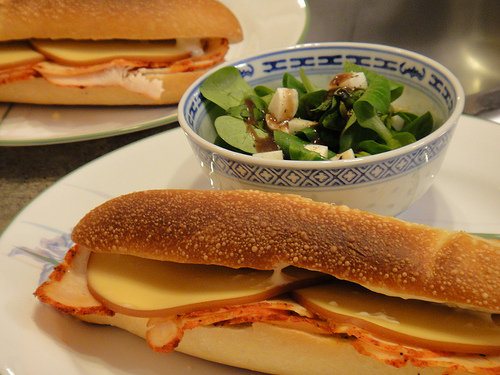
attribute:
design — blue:
[383, 144, 415, 180]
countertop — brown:
[13, 177, 25, 186]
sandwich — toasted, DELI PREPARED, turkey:
[38, 191, 499, 372]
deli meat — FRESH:
[3, 37, 191, 79]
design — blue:
[247, 171, 402, 185]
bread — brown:
[292, 216, 369, 256]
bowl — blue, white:
[176, 40, 481, 217]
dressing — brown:
[243, 99, 275, 154]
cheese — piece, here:
[393, 317, 466, 342]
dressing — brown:
[229, 67, 374, 157]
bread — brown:
[70, 186, 499, 314]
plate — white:
[62, 179, 74, 186]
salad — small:
[204, 65, 439, 174]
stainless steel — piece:
[429, 27, 496, 101]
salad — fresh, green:
[214, 71, 419, 147]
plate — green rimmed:
[0, 0, 310, 147]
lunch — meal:
[33, 35, 471, 371]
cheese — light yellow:
[99, 241, 247, 321]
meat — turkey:
[30, 245, 497, 372]